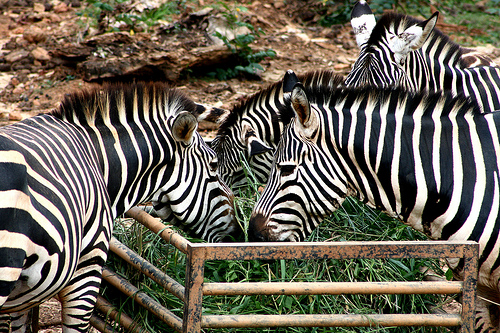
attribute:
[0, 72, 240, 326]
zebra — white, black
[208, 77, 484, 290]
zebra — white, black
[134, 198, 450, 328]
grass — green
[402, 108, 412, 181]
skin — black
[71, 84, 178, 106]
zebra's mane — brown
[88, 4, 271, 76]
tree — in the back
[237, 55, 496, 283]
zebra — white, black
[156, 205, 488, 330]
gate — iron 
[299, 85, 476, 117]
mane — black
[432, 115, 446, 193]
skin — white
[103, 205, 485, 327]
fence — shabby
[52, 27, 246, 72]
brown rock — brown 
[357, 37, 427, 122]
zebra — black, white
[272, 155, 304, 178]
eye — black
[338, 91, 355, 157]
stripes — black, white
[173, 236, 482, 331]
fence — wooden , brown 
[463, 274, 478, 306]
marks — black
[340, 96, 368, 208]
stripe — black, white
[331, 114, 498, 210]
stripes — black, white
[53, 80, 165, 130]
mane — thick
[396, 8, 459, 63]
mane — thick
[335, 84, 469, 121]
mane — thick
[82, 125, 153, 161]
stripes — white, black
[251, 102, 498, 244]
zebra — black, white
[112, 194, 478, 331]
trough — metal